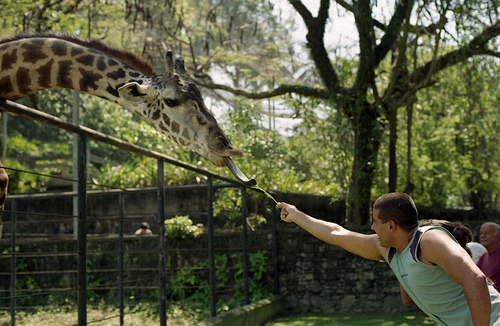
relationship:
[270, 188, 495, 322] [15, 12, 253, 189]
man feed giraffe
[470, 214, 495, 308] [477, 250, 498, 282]
man wearing a shirt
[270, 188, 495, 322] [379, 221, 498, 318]
man wearing shirt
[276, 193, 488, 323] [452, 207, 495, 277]
people standing people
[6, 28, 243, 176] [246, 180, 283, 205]
giraffe licking leaf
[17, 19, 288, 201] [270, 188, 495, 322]
giraffe fed by man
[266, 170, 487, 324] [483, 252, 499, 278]
man wearing pink shirt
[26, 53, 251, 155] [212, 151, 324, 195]
giraffe has tongue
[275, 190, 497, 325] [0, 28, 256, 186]
boy trying to feed giraffe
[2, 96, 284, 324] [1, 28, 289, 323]
fence enclosing giraffe compound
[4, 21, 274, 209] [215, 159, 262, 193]
giraffe reaching with tongue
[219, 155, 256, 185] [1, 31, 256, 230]
tongue of giraffe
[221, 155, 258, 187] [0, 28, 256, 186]
tongue of giraffe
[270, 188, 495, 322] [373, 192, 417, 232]
man has hair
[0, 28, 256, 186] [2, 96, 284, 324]
giraffe behind fence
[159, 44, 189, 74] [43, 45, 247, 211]
horns of giraffe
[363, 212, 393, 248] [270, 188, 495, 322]
face of man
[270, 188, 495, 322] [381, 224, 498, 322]
man wearing a tank top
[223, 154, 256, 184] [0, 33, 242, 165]
tongue of giraffe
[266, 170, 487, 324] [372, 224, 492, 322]
man wearing a shirt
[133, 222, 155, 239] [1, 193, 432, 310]
man looking on ledge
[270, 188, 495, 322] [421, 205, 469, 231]
man has backpack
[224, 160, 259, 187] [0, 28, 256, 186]
tongue of giraffe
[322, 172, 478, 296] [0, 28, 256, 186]
man feeding giraffe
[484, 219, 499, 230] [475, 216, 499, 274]
gray hair on elderly man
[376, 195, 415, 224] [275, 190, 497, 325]
haircut on boy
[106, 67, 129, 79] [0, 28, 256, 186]
spot on giraffe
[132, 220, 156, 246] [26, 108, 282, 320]
person standing behind fence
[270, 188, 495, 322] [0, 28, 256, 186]
man feeling giraffe